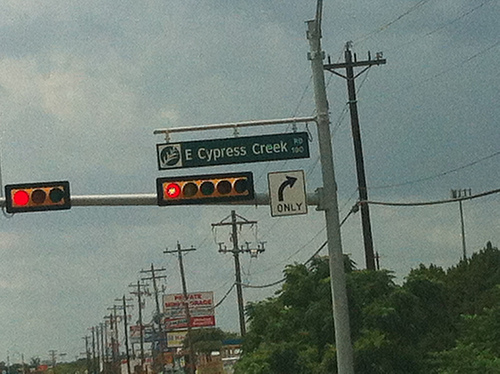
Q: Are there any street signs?
A: Yes, there is a street sign.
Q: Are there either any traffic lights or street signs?
A: Yes, there is a street sign.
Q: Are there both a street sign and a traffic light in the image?
A: Yes, there are both a street sign and a traffic light.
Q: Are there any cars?
A: No, there are no cars.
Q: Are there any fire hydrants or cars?
A: No, there are no cars or fire hydrants.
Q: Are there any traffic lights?
A: Yes, there is a traffic light.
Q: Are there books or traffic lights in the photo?
A: Yes, there is a traffic light.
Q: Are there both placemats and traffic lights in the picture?
A: No, there is a traffic light but no placemats.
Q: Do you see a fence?
A: No, there are no fences.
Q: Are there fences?
A: No, there are no fences.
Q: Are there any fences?
A: No, there are no fences.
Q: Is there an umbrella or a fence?
A: No, there are no fences or umbrellas.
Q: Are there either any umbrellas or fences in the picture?
A: No, there are no fences or umbrellas.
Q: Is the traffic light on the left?
A: Yes, the traffic light is on the left of the image.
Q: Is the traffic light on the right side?
A: No, the traffic light is on the left of the image.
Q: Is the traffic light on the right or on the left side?
A: The traffic light is on the left of the image.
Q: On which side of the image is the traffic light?
A: The traffic light is on the left of the image.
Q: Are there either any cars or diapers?
A: No, there are no cars or diapers.